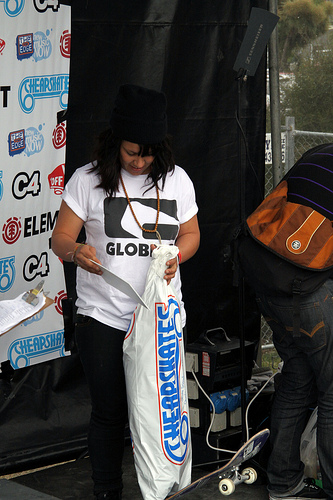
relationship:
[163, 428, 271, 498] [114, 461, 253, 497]
skateboard on ground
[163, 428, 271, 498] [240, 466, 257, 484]
skateboard has wheels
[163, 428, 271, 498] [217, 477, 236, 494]
skateboard has wheels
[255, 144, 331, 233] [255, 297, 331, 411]
person wearing jeans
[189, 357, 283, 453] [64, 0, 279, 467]
wire hanging from equipment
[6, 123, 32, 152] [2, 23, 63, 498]
emblem on side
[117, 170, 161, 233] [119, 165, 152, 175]
necklace worn around neck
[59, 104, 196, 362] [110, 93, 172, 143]
person wearing a hat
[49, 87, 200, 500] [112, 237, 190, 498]
girl holding bag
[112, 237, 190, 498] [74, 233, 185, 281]
bag in her hands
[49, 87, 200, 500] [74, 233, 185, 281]
girl holding bag in her hands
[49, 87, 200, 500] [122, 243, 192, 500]
girl holding bag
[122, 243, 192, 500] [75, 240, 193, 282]
bag in her hands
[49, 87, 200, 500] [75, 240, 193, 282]
girl holding bag in her hands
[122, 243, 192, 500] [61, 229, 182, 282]
bag in her hands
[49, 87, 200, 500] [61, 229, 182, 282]
girl holding bag in her hands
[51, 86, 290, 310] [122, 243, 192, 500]
girl holding bag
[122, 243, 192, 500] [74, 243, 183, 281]
bag in her hands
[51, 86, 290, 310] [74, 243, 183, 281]
girl holding bag in her hands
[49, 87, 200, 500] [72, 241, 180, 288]
girl holding bag in her hands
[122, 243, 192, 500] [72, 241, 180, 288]
bag in her hands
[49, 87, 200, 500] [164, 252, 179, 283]
girl holding a bag in her hand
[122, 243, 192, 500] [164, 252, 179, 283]
bag hand hand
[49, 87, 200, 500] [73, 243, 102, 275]
girl holding a bag in her hand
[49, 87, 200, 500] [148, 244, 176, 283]
girl holding a bag in her hand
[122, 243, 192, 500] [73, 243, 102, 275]
bag in her hand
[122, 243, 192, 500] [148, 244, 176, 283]
bag in her hand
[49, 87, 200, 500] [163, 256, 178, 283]
girl bag in her hand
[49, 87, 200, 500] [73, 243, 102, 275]
girl bag in her hand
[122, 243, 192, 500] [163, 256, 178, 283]
bag in her hand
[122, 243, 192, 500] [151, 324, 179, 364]
bag with letters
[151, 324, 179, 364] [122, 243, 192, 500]
letters on bag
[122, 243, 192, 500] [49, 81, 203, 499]
bag in hands of woman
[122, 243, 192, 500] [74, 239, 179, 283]
bag in hands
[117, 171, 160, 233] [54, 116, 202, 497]
necklace on woman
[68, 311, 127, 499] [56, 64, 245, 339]
pants on woman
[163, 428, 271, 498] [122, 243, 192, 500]
skateboard under bag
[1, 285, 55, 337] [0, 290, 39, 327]
clipboard with papers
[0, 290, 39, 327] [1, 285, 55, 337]
papers on clipboard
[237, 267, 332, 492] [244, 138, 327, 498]
jeans on person